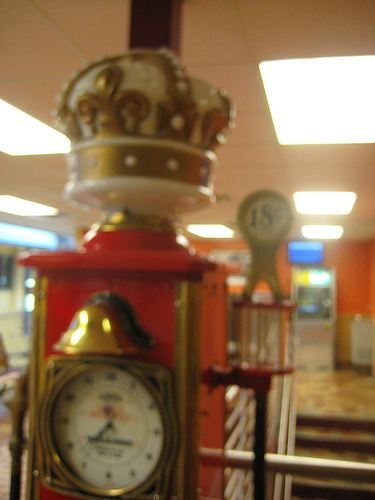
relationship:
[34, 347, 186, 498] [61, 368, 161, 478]
clock has numbers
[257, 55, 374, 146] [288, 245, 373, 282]
light on wall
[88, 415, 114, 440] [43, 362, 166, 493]
black hand on clock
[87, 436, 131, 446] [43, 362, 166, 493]
black writing on clock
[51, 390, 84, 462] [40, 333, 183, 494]
numbers on clock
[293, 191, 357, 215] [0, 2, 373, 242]
light in ceiling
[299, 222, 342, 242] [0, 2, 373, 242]
light in ceiling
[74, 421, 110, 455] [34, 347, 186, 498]
black hand on clock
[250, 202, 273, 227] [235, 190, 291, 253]
number on sign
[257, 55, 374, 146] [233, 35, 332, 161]
light on ceiling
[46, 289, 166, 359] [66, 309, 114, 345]
bell with lights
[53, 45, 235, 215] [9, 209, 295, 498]
crown on top of candy machine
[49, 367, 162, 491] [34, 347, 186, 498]
face of clock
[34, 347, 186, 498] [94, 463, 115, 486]
clock with numbers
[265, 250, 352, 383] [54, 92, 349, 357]
doorway of store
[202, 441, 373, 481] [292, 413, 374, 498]
rail over staircase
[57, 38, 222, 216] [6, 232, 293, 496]
crown on top of clock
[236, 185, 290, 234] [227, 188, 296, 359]
number on a post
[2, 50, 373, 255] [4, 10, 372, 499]
light of room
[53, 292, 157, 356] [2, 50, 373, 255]
bell reflects light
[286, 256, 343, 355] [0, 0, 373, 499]
door of store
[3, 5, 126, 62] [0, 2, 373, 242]
tile on ceiling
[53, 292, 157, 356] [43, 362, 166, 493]
bell above clock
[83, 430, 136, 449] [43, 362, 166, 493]
black writing on clock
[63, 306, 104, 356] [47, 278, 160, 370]
light shining on bell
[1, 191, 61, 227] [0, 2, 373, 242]
light shining on ceiling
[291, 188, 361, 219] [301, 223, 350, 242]
light on light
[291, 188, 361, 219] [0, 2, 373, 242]
light on ceiling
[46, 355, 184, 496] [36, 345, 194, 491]
numbers around clock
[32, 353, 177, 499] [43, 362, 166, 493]
gold circle around clock